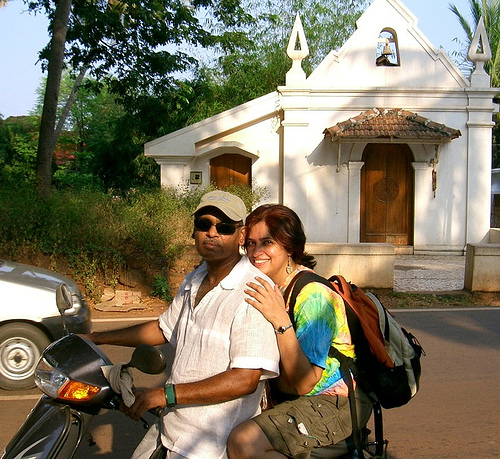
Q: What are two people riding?
A: Motorbike.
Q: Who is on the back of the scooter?
A: A woman.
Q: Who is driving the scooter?
A: A man .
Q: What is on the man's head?
A: A beige hat.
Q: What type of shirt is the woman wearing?
A: A tie dye shirt.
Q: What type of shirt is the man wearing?
A: A white shirt.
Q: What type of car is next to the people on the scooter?
A: A silver car.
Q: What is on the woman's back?
A: A backpack.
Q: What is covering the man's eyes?
A: Sunglasses.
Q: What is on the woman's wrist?
A: A watch.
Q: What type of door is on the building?
A: A wooden door.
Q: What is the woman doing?
A: Riding on the back of a scooter.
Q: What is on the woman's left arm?
A: A watch.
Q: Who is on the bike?
A: A couple.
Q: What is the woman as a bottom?
A: Shorts.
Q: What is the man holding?
A: Handles.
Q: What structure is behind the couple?
A: A chruch.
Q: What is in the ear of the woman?
A: An earring.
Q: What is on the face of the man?
A: Sunglasses.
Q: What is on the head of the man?
A: A hat.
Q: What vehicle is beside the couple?
A: A car.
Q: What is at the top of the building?
A: A bell.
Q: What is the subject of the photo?
A: People.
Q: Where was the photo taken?
A: Street.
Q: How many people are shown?
A: Two.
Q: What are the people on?
A: Scooter.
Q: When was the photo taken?
A: Daytime.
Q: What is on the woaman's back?
A: Backpack.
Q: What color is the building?
A: Whitre.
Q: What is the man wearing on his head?
A: Hat.